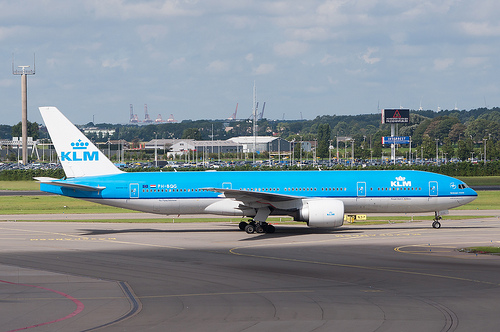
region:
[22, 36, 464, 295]
a plane on the ground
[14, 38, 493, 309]
an airplane on the ground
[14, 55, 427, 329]
a blue airplane with white tail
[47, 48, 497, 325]
a blue plane with white tail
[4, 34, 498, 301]
an airplane at the airport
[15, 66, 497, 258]
a plane on the runway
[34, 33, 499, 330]
an airplane on the runway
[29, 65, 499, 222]
a blue plne on the ground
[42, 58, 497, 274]
a blue airplane on the road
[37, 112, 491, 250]
blue and white airplane on runway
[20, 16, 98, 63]
white clouds against blue sky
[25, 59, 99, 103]
white clouds against blue sky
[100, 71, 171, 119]
white clouds against blue sky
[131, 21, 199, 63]
white clouds against blue sky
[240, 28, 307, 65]
white clouds against blue sky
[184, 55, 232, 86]
white clouds against blue sky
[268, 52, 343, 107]
white clouds against blue sky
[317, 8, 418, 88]
white clouds against blue sky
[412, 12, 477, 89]
white clouds against blue sky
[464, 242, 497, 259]
a section of green grass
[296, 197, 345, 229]
a large plane engine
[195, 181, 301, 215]
the wing of a plane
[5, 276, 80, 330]
a large pink line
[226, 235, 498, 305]
a large yellow line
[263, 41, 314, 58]
a small white cloud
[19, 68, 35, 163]
a tall brown pole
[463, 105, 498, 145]
a tall green tree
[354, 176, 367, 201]
the door of a plane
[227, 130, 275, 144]
the roof of a building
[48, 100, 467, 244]
blue and white airplane on run way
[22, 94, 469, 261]
blue and white airplane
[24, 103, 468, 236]
airplane on run way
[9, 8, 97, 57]
white clouds in blue sky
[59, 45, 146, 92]
white clouds in blue sky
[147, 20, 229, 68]
white clouds in blue sky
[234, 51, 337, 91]
white clouds in blue sky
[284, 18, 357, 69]
white clouds in blue sky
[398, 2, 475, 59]
white clouds in blue sky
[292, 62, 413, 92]
white clouds in blue sky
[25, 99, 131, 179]
tail of an airplane with the logo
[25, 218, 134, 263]
painted lines on runway to guide planes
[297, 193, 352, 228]
engine of a plane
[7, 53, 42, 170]
a radio control tower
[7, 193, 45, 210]
rass bordering the airport runway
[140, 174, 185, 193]
airplane's identification number and flag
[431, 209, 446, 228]
front landing gear on an airplane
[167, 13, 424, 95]
cloudy sky outsie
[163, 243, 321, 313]
asphalt airport runway